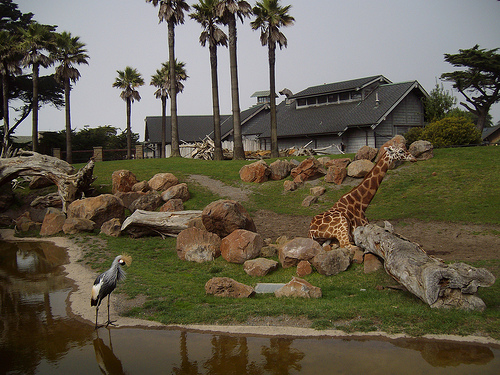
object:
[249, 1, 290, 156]
trees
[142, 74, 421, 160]
building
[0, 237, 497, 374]
water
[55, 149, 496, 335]
grass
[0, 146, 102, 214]
log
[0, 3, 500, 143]
sky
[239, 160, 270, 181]
boulders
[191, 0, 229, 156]
trees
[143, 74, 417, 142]
roof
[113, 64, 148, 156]
tree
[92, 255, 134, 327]
bird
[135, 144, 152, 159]
stone posts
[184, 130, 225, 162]
pile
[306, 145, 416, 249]
giraffe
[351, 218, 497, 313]
log